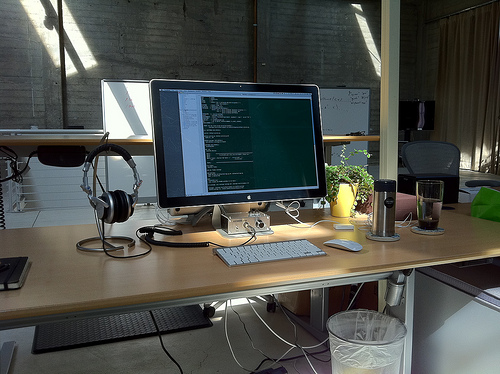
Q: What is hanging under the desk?
A: Cords.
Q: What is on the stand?
A: A headset.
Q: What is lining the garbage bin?
A: Plastic.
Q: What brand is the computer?
A: Apple.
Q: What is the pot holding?
A: A plant.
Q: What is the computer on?
A: A desk.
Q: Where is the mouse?
A: Next to the keyboard.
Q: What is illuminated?
A: Computer monitor.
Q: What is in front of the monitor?
A: Keyboard.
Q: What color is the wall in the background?
A: Gray.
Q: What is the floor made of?
A: Concrete.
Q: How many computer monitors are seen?
A: One.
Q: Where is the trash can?
A: Under desk.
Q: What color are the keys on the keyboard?
A: White.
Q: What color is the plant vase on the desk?
A: Yellow.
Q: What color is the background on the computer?
A: Black.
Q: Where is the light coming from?
A: Sun.